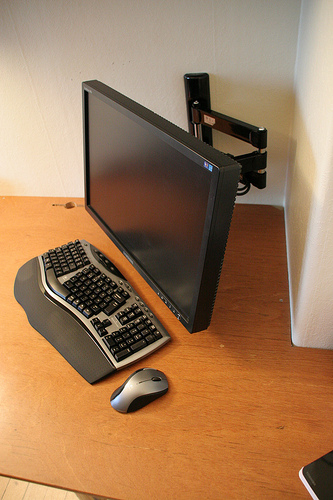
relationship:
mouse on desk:
[107, 363, 169, 416] [2, 190, 324, 494]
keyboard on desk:
[11, 236, 174, 387] [2, 190, 324, 494]